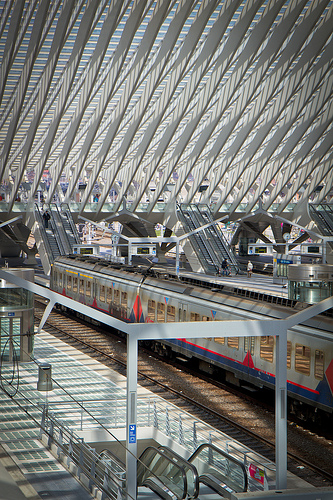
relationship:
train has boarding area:
[49, 253, 330, 408] [153, 259, 331, 304]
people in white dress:
[247, 259, 253, 278] [247, 263, 253, 272]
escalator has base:
[177, 202, 218, 274] [206, 265, 226, 278]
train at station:
[49, 253, 330, 408] [2, 5, 329, 499]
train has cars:
[49, 253, 330, 408] [47, 259, 326, 416]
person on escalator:
[43, 209, 53, 230] [35, 205, 61, 272]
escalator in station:
[177, 202, 218, 274] [2, 5, 329, 499]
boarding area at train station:
[235, 277, 331, 304] [8, 131, 309, 494]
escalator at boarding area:
[177, 202, 218, 274] [235, 277, 331, 304]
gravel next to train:
[50, 314, 321, 479] [49, 253, 330, 408]